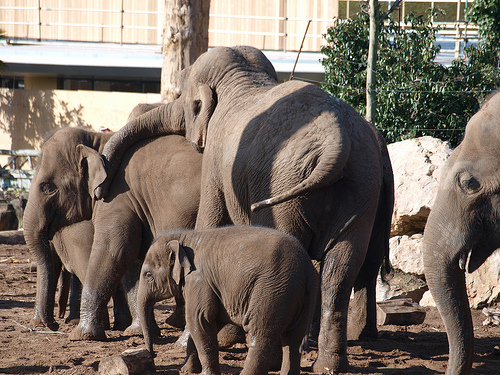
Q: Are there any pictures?
A: No, there are no pictures.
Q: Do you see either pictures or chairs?
A: No, there are no pictures or chairs.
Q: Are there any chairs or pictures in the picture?
A: No, there are no pictures or chairs.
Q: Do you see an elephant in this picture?
A: Yes, there is an elephant.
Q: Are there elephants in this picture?
A: Yes, there is an elephant.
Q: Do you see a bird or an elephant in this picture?
A: Yes, there is an elephant.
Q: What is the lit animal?
A: The animal is an elephant.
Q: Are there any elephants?
A: Yes, there is an elephant.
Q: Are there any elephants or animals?
A: Yes, there is an elephant.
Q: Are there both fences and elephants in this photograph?
A: Yes, there are both an elephant and a fence.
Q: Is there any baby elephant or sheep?
A: Yes, there is a baby elephant.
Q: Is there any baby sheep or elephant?
A: Yes, there is a baby elephant.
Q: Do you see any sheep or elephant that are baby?
A: Yes, the elephant is a baby.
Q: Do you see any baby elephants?
A: Yes, there is a baby elephant.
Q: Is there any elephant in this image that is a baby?
A: Yes, there is an elephant that is a baby.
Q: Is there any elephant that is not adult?
A: Yes, there is an baby elephant.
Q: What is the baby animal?
A: The animal is an elephant.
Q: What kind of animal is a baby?
A: The animal is an elephant.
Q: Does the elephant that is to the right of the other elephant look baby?
A: Yes, the elephant is a baby.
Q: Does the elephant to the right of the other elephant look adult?
A: No, the elephant is a baby.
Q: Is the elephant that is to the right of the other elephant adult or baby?
A: The elephant is a baby.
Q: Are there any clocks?
A: No, there are no clocks.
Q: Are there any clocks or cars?
A: No, there are no clocks or cars.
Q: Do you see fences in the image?
A: Yes, there is a fence.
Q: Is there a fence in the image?
A: Yes, there is a fence.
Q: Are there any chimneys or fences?
A: Yes, there is a fence.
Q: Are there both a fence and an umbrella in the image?
A: No, there is a fence but no umbrellas.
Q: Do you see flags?
A: No, there are no flags.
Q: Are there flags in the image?
A: No, there are no flags.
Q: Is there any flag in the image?
A: No, there are no flags.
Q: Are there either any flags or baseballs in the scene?
A: No, there are no flags or baseballs.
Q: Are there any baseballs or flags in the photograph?
A: No, there are no flags or baseballs.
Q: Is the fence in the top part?
A: Yes, the fence is in the top of the image.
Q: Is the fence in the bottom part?
A: No, the fence is in the top of the image.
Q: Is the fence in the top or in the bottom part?
A: The fence is in the top of the image.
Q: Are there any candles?
A: No, there are no candles.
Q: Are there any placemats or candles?
A: No, there are no candles or placemats.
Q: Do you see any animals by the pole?
A: Yes, there are animals by the pole.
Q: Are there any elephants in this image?
A: Yes, there is an elephant.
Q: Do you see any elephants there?
A: Yes, there is an elephant.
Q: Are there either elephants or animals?
A: Yes, there is an elephant.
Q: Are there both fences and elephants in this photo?
A: Yes, there are both an elephant and a fence.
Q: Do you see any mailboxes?
A: No, there are no mailboxes.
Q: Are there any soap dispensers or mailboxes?
A: No, there are no mailboxes or soap dispensers.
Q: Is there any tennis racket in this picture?
A: No, there are no rackets.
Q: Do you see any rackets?
A: No, there are no rackets.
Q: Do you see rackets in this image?
A: No, there are no rackets.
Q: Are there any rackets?
A: No, there are no rackets.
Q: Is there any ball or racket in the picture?
A: No, there are no rackets or balls.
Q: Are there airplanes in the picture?
A: No, there are no airplanes.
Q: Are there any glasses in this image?
A: No, there are no glasses.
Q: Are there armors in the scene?
A: No, there are no armors.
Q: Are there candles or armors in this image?
A: No, there are no armors or candles.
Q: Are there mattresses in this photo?
A: No, there are no mattresses.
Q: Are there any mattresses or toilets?
A: No, there are no mattresses or toilets.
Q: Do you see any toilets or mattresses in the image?
A: No, there are no mattresses or toilets.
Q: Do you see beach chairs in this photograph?
A: No, there are no beach chairs.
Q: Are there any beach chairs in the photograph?
A: No, there are no beach chairs.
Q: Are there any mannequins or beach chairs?
A: No, there are no beach chairs or mannequins.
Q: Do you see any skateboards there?
A: No, there are no skateboards.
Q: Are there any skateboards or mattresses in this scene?
A: No, there are no skateboards or mattresses.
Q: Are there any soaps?
A: No, there are no soaps.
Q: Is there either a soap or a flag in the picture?
A: No, there are no soaps or flags.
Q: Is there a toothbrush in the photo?
A: No, there are no toothbrushes.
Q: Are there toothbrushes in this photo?
A: No, there are no toothbrushes.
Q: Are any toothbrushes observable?
A: No, there are no toothbrushes.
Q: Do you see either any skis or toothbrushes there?
A: No, there are no toothbrushes or skis.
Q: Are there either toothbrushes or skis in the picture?
A: No, there are no toothbrushes or skis.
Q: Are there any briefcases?
A: No, there are no briefcases.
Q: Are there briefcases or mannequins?
A: No, there are no briefcases or mannequins.